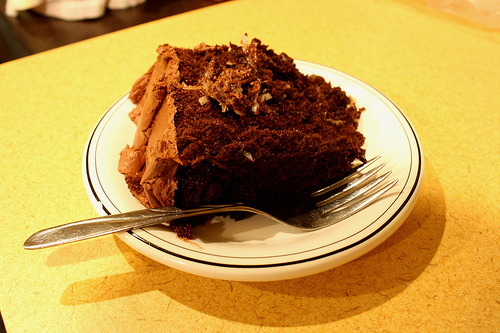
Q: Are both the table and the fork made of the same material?
A: No, the table is made of wood and the fork is made of metal.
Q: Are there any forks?
A: Yes, there is a fork.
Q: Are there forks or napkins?
A: Yes, there is a fork.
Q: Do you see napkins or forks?
A: Yes, there is a fork.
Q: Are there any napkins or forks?
A: Yes, there is a fork.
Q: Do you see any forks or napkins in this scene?
A: Yes, there is a fork.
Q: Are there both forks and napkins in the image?
A: No, there is a fork but no napkins.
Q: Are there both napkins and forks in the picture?
A: No, there is a fork but no napkins.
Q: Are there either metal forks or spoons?
A: Yes, there is a metal fork.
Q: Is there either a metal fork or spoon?
A: Yes, there is a metal fork.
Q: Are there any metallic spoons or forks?
A: Yes, there is a metal fork.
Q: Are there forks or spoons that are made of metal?
A: Yes, the fork is made of metal.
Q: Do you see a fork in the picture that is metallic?
A: Yes, there is a metal fork.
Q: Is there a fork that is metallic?
A: Yes, there is a fork that is metallic.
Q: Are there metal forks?
A: Yes, there is a fork that is made of metal.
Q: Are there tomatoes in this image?
A: No, there are no tomatoes.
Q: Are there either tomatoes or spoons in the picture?
A: No, there are no tomatoes or spoons.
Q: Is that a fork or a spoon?
A: That is a fork.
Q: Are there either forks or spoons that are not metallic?
A: No, there is a fork but it is metallic.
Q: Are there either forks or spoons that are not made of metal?
A: No, there is a fork but it is made of metal.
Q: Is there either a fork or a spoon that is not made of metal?
A: No, there is a fork but it is made of metal.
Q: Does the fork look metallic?
A: Yes, the fork is metallic.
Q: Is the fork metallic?
A: Yes, the fork is metallic.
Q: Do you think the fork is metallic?
A: Yes, the fork is metallic.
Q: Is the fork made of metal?
A: Yes, the fork is made of metal.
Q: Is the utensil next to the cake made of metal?
A: Yes, the fork is made of metal.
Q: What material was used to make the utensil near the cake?
A: The fork is made of metal.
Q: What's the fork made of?
A: The fork is made of metal.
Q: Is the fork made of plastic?
A: No, the fork is made of metal.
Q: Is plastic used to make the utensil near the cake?
A: No, the fork is made of metal.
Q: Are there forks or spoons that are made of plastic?
A: No, there is a fork but it is made of metal.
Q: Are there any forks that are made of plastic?
A: No, there is a fork but it is made of metal.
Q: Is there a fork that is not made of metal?
A: No, there is a fork but it is made of metal.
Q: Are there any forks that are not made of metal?
A: No, there is a fork but it is made of metal.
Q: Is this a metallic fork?
A: Yes, this is a metallic fork.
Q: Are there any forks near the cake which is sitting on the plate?
A: Yes, there is a fork near the cake.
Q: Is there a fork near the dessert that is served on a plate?
A: Yes, there is a fork near the cake.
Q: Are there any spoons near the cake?
A: No, there is a fork near the cake.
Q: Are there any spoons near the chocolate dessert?
A: No, there is a fork near the cake.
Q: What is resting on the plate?
A: The fork is resting on the plate.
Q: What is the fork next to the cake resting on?
A: The fork is resting on the plate.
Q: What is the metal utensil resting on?
A: The fork is resting on the plate.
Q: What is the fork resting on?
A: The fork is resting on the plate.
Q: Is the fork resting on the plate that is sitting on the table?
A: Yes, the fork is resting on the plate.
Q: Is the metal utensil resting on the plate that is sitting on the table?
A: Yes, the fork is resting on the plate.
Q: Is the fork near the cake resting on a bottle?
A: No, the fork is resting on the plate.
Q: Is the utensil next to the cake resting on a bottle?
A: No, the fork is resting on the plate.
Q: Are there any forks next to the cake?
A: Yes, there is a fork next to the cake.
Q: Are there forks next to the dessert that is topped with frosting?
A: Yes, there is a fork next to the cake.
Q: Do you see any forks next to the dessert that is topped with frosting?
A: Yes, there is a fork next to the cake.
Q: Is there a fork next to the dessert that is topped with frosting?
A: Yes, there is a fork next to the cake.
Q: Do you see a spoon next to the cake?
A: No, there is a fork next to the cake.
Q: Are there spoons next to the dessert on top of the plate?
A: No, there is a fork next to the cake.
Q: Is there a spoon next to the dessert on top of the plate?
A: No, there is a fork next to the cake.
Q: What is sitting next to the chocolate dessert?
A: The fork is sitting next to the cake.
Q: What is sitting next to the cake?
A: The fork is sitting next to the cake.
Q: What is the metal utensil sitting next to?
A: The fork is sitting next to the cake.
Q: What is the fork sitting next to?
A: The fork is sitting next to the cake.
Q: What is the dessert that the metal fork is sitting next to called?
A: The dessert is a cake.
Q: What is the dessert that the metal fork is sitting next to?
A: The dessert is a cake.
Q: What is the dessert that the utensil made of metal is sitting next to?
A: The dessert is a cake.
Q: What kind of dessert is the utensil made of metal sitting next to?
A: The fork is sitting next to the cake.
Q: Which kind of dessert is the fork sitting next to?
A: The fork is sitting next to the cake.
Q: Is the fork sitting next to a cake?
A: Yes, the fork is sitting next to a cake.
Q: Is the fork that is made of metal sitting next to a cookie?
A: No, the fork is sitting next to a cake.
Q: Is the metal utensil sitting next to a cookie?
A: No, the fork is sitting next to a cake.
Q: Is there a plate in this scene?
A: Yes, there is a plate.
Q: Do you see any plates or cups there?
A: Yes, there is a plate.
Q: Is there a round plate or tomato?
A: Yes, there is a round plate.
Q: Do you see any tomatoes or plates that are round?
A: Yes, the plate is round.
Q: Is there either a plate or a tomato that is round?
A: Yes, the plate is round.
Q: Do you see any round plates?
A: Yes, there is a round plate.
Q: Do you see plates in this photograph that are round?
A: Yes, there is a plate that is round.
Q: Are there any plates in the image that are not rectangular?
A: Yes, there is a round plate.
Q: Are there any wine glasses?
A: No, there are no wine glasses.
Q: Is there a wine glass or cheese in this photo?
A: No, there are no wine glasses or cheese.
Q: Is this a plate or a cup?
A: This is a plate.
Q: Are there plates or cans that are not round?
A: No, there is a plate but it is round.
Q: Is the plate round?
A: Yes, the plate is round.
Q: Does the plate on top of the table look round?
A: Yes, the plate is round.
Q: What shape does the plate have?
A: The plate has round shape.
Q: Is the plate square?
A: No, the plate is round.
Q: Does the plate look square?
A: No, the plate is round.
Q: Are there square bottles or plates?
A: No, there is a plate but it is round.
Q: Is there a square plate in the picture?
A: No, there is a plate but it is round.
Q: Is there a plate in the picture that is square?
A: No, there is a plate but it is round.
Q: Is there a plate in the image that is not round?
A: No, there is a plate but it is round.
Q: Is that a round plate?
A: Yes, that is a round plate.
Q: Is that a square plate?
A: No, that is a round plate.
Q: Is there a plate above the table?
A: Yes, there is a plate above the table.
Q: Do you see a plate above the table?
A: Yes, there is a plate above the table.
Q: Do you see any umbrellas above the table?
A: No, there is a plate above the table.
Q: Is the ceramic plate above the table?
A: Yes, the plate is above the table.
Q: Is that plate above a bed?
A: No, the plate is above the table.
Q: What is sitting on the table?
A: The plate is sitting on the table.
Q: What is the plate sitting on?
A: The plate is sitting on the table.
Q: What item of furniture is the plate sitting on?
A: The plate is sitting on the table.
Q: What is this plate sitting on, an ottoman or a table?
A: The plate is sitting on a table.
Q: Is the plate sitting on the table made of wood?
A: Yes, the plate is sitting on the table.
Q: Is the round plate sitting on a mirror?
A: No, the plate is sitting on the table.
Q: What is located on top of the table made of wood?
A: The plate is on top of the table.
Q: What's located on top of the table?
A: The plate is on top of the table.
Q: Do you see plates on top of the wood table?
A: Yes, there is a plate on top of the table.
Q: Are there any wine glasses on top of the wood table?
A: No, there is a plate on top of the table.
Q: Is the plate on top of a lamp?
A: No, the plate is on top of the table.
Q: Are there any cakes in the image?
A: Yes, there is a cake.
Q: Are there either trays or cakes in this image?
A: Yes, there is a cake.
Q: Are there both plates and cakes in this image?
A: Yes, there are both a cake and a plate.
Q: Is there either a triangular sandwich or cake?
A: Yes, there is a triangular cake.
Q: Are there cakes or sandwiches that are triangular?
A: Yes, the cake is triangular.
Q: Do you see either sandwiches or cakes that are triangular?
A: Yes, the cake is triangular.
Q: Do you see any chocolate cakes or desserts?
A: Yes, there is a chocolate cake.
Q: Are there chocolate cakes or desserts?
A: Yes, there is a chocolate cake.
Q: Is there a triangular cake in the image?
A: Yes, there is a triangular cake.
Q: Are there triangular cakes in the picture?
A: Yes, there is a triangular cake.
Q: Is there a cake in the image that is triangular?
A: Yes, there is a cake that is triangular.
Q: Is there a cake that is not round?
A: Yes, there is a triangular cake.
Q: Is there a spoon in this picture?
A: No, there are no spoons.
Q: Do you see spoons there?
A: No, there are no spoons.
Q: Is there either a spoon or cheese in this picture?
A: No, there are no spoons or cheese.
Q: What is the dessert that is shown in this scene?
A: The dessert is a cake.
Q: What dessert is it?
A: The dessert is a cake.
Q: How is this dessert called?
A: That is a cake.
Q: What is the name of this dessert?
A: That is a cake.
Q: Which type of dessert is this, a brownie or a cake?
A: That is a cake.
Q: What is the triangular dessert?
A: The dessert is a cake.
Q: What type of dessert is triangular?
A: The dessert is a cake.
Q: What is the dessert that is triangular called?
A: The dessert is a cake.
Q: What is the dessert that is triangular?
A: The dessert is a cake.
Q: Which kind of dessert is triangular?
A: The dessert is a cake.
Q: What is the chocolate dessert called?
A: The dessert is a cake.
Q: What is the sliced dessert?
A: The dessert is a cake.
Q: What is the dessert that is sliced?
A: The dessert is a cake.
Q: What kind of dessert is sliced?
A: The dessert is a cake.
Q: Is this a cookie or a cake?
A: This is a cake.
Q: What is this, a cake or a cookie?
A: This is a cake.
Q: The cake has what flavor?
A: This is a chocolate cake.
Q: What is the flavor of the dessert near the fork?
A: This is a chocolate cake.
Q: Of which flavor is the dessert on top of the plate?
A: This is a chocolate cake.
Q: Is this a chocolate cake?
A: Yes, this is a chocolate cake.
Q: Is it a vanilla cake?
A: No, this is a chocolate cake.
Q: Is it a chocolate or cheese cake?
A: This is a chocolate cake.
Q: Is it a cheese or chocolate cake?
A: This is a chocolate cake.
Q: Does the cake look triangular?
A: Yes, the cake is triangular.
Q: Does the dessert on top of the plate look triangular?
A: Yes, the cake is triangular.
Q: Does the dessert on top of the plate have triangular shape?
A: Yes, the cake is triangular.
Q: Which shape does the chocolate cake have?
A: The cake has triangular shape.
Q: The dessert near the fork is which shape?
A: The cake is triangular.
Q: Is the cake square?
A: No, the cake is triangular.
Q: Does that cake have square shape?
A: No, the cake is triangular.